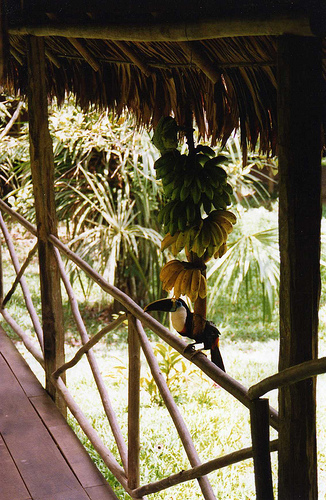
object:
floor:
[0, 326, 119, 500]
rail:
[0, 199, 278, 433]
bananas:
[176, 232, 187, 252]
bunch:
[153, 144, 227, 201]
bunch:
[157, 195, 197, 237]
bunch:
[159, 210, 236, 259]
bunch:
[160, 258, 208, 299]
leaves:
[238, 66, 263, 131]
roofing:
[0, 1, 325, 156]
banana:
[161, 234, 178, 251]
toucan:
[144, 298, 227, 375]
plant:
[155, 341, 182, 383]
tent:
[0, 0, 320, 496]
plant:
[205, 140, 275, 209]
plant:
[64, 165, 163, 294]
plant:
[52, 98, 120, 155]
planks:
[0, 430, 33, 500]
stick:
[133, 438, 279, 499]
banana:
[201, 228, 211, 248]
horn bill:
[143, 297, 175, 314]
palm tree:
[207, 206, 279, 321]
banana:
[160, 260, 181, 281]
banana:
[163, 264, 185, 290]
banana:
[174, 270, 186, 300]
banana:
[181, 270, 193, 296]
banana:
[192, 270, 202, 292]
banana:
[190, 186, 201, 204]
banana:
[187, 203, 195, 223]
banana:
[211, 220, 225, 249]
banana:
[191, 268, 201, 290]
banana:
[206, 184, 214, 199]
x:
[53, 247, 127, 475]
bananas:
[199, 274, 207, 299]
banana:
[210, 210, 236, 225]